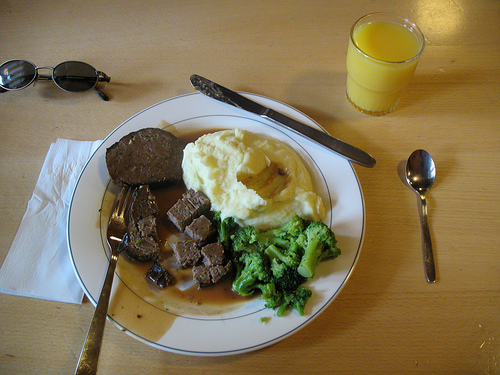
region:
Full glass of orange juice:
[327, 6, 427, 120]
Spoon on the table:
[403, 145, 445, 287]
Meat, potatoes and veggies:
[66, 73, 372, 354]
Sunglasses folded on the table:
[1, 45, 115, 104]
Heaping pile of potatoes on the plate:
[180, 124, 330, 231]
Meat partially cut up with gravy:
[103, 125, 230, 289]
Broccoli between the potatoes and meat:
[206, 205, 346, 318]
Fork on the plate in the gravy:
[64, 180, 143, 373]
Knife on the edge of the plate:
[186, 70, 378, 169]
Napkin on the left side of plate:
[1, 131, 102, 314]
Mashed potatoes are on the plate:
[180, 127, 329, 232]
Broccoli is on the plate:
[213, 212, 335, 314]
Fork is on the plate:
[72, 180, 145, 373]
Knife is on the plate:
[188, 70, 378, 171]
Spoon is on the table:
[402, 142, 444, 285]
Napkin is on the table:
[1, 130, 106, 307]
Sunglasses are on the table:
[1, 57, 116, 103]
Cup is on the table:
[340, 9, 429, 119]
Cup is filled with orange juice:
[343, 9, 427, 117]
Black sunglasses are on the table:
[0, 57, 115, 105]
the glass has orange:
[324, 13, 428, 121]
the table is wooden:
[438, 92, 498, 194]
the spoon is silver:
[381, 148, 479, 291]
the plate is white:
[59, 88, 358, 346]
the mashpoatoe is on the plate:
[183, 126, 314, 211]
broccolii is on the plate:
[236, 224, 347, 303]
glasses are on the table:
[4, 56, 111, 96]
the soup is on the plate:
[101, 130, 311, 288]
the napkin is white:
[40, 150, 65, 299]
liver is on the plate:
[125, 198, 244, 288]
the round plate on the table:
[68, 87, 366, 356]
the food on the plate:
[106, 128, 336, 314]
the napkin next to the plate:
[4, 135, 101, 305]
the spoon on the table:
[407, 148, 442, 283]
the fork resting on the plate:
[73, 185, 139, 374]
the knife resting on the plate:
[189, 73, 377, 167]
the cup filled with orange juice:
[346, 11, 424, 117]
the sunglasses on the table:
[0, 58, 112, 101]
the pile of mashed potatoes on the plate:
[182, 128, 326, 223]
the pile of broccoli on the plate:
[212, 214, 334, 314]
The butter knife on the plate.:
[190, 70, 390, 192]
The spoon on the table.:
[397, 142, 444, 287]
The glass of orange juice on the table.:
[340, 12, 429, 119]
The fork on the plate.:
[72, 175, 139, 374]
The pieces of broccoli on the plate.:
[220, 220, 336, 310]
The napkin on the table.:
[12, 130, 104, 308]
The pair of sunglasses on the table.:
[6, 58, 123, 110]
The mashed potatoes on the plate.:
[187, 114, 329, 231]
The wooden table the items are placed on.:
[2, 1, 498, 373]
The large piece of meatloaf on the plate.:
[101, 128, 181, 180]